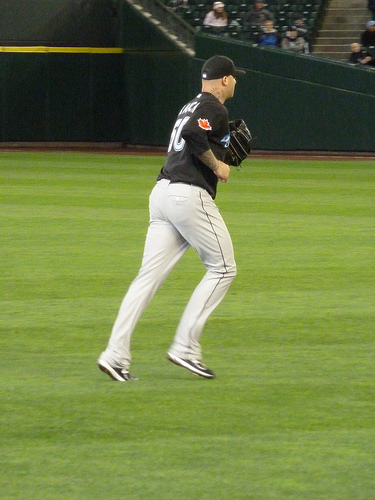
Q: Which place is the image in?
A: It is at the stadium.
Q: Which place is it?
A: It is a stadium.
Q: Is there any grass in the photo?
A: Yes, there is grass.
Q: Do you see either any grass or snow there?
A: Yes, there is grass.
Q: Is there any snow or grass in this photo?
A: Yes, there is grass.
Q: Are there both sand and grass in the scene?
A: No, there is grass but no sand.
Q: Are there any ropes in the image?
A: No, there are no ropes.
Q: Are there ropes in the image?
A: No, there are no ropes.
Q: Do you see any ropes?
A: No, there are no ropes.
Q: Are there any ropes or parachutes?
A: No, there are no ropes or parachutes.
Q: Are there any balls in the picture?
A: No, there are no balls.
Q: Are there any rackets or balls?
A: No, there are no balls or rackets.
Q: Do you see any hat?
A: Yes, there is a hat.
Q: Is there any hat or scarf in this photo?
A: Yes, there is a hat.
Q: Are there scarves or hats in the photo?
A: Yes, there is a hat.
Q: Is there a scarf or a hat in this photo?
A: Yes, there is a hat.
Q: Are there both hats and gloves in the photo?
A: Yes, there are both a hat and gloves.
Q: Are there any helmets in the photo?
A: No, there are no helmets.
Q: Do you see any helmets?
A: No, there are no helmets.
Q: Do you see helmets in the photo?
A: No, there are no helmets.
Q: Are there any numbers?
A: Yes, there are numbers.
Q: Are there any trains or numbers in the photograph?
A: Yes, there are numbers.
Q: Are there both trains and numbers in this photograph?
A: No, there are numbers but no trains.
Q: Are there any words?
A: No, there are no words.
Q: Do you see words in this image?
A: No, there are no words.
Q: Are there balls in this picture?
A: No, there are no balls.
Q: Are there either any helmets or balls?
A: No, there are no balls or helmets.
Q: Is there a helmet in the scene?
A: No, there are no helmets.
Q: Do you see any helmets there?
A: No, there are no helmets.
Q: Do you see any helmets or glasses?
A: No, there are no helmets or glasses.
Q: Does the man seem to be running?
A: Yes, the man is running.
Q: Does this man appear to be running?
A: Yes, the man is running.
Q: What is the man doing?
A: The man is running.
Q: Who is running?
A: The man is running.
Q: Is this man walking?
A: No, the man is running.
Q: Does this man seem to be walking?
A: No, the man is running.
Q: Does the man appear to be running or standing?
A: The man is running.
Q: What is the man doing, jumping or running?
A: The man is running.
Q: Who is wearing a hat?
A: The man is wearing a hat.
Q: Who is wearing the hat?
A: The man is wearing a hat.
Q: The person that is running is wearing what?
A: The man is wearing a hat.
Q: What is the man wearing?
A: The man is wearing a hat.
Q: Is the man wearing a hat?
A: Yes, the man is wearing a hat.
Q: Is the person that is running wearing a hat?
A: Yes, the man is wearing a hat.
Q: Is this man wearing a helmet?
A: No, the man is wearing a hat.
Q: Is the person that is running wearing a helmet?
A: No, the man is wearing a hat.